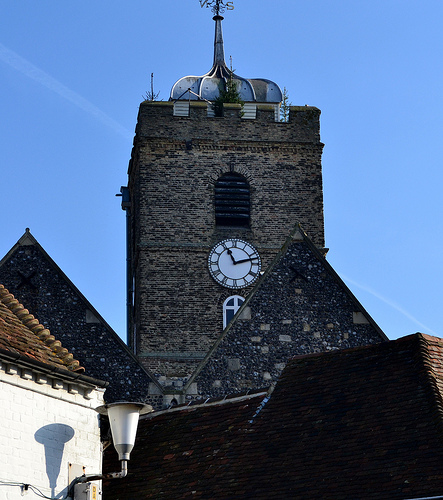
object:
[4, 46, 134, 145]
white line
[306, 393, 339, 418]
brick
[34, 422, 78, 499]
shadow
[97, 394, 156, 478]
street light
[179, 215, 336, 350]
clock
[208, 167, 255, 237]
window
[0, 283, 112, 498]
building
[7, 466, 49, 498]
lamp wire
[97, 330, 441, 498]
roof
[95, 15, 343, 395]
tower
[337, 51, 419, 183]
sky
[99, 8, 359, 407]
building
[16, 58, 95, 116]
clouds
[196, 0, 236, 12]
weather vane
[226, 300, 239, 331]
window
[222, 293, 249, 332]
trim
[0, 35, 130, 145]
contrail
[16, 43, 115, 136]
sky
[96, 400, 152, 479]
fixture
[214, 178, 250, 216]
slats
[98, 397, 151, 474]
light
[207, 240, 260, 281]
time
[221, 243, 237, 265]
hand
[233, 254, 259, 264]
hand